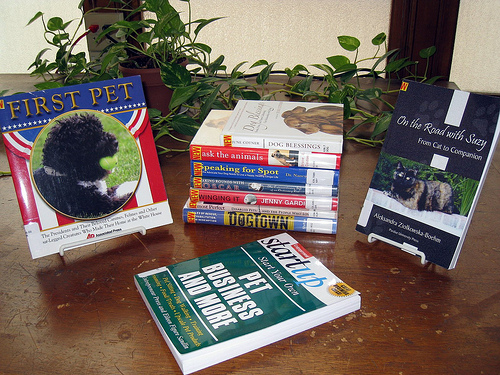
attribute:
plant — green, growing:
[20, 0, 393, 145]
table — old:
[1, 70, 496, 374]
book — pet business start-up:
[127, 228, 364, 371]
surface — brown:
[2, 72, 499, 372]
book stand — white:
[55, 225, 154, 258]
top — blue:
[2, 67, 148, 127]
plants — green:
[17, 4, 417, 149]